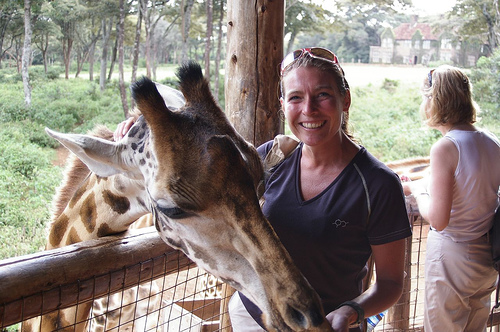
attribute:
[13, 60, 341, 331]
giraffe — spotted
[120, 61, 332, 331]
head — big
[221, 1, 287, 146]
post — sturdy, wooden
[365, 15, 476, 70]
building — distant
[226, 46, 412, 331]
woman — smiling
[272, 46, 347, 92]
sunglasses — small, red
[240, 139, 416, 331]
shirt — blue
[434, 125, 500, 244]
shirt — white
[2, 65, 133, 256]
bushes — green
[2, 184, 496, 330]
fence — wire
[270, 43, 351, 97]
hair — pulled back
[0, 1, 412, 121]
trees — green